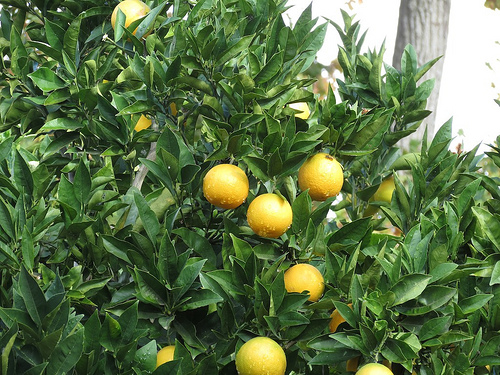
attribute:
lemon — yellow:
[201, 159, 249, 213]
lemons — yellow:
[143, 127, 435, 374]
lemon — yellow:
[296, 149, 346, 201]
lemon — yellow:
[246, 191, 292, 239]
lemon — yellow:
[202, 160, 249, 207]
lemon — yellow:
[278, 261, 325, 303]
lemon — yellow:
[232, 332, 291, 374]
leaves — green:
[22, 48, 197, 299]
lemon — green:
[196, 155, 348, 245]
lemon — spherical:
[300, 155, 348, 200]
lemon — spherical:
[248, 192, 298, 242]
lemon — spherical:
[200, 161, 252, 210]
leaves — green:
[36, 67, 164, 281]